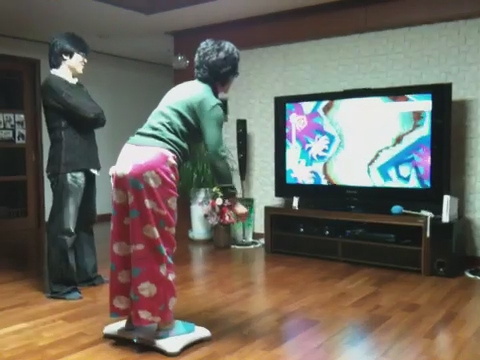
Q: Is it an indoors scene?
A: Yes, it is indoors.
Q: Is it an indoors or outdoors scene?
A: It is indoors.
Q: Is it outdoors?
A: No, it is indoors.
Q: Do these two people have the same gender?
A: No, they are both male and female.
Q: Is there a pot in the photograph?
A: Yes, there is a pot.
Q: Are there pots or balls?
A: Yes, there is a pot.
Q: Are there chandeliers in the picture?
A: No, there are no chandeliers.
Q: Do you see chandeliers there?
A: No, there are no chandeliers.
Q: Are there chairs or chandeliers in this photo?
A: No, there are no chandeliers or chairs.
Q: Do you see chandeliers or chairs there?
A: No, there are no chandeliers or chairs.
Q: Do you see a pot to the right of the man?
A: Yes, there is a pot to the right of the man.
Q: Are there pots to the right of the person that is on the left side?
A: Yes, there is a pot to the right of the man.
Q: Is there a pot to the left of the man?
A: No, the pot is to the right of the man.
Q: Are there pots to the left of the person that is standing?
A: No, the pot is to the right of the man.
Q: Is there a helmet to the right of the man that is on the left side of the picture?
A: No, there is a pot to the right of the man.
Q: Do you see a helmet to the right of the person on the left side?
A: No, there is a pot to the right of the man.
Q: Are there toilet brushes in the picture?
A: No, there are no toilet brushes.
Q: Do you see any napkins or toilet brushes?
A: No, there are no toilet brushes or napkins.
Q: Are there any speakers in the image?
A: Yes, there is a speaker.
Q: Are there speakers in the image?
A: Yes, there is a speaker.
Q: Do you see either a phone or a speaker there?
A: Yes, there is a speaker.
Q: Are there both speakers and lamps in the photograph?
A: No, there is a speaker but no lamps.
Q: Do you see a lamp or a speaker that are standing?
A: Yes, the speaker is standing.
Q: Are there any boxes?
A: No, there are no boxes.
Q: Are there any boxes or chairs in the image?
A: No, there are no boxes or chairs.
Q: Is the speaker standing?
A: Yes, the speaker is standing.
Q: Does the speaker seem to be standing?
A: Yes, the speaker is standing.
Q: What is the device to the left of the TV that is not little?
A: The device is a speaker.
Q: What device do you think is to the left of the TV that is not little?
A: The device is a speaker.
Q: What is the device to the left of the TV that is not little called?
A: The device is a speaker.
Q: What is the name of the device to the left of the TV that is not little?
A: The device is a speaker.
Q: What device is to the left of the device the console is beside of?
A: The device is a speaker.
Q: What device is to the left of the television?
A: The device is a speaker.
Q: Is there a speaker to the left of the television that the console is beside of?
A: Yes, there is a speaker to the left of the TV.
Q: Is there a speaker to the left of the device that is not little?
A: Yes, there is a speaker to the left of the TV.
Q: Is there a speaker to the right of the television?
A: No, the speaker is to the left of the television.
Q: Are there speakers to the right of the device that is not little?
A: No, the speaker is to the left of the television.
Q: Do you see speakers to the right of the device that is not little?
A: No, the speaker is to the left of the television.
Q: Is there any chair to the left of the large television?
A: No, there is a speaker to the left of the television.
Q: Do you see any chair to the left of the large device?
A: No, there is a speaker to the left of the television.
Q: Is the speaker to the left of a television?
A: Yes, the speaker is to the left of a television.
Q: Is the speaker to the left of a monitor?
A: No, the speaker is to the left of a television.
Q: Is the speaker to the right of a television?
A: No, the speaker is to the left of a television.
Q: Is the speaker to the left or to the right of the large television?
A: The speaker is to the left of the TV.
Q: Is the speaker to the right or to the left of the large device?
A: The speaker is to the left of the TV.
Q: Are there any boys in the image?
A: No, there are no boys.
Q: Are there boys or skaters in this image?
A: No, there are no boys or skaters.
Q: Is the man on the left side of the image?
A: Yes, the man is on the left of the image.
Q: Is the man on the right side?
A: No, the man is on the left of the image.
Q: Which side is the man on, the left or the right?
A: The man is on the left of the image.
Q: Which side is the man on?
A: The man is on the left of the image.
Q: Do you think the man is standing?
A: Yes, the man is standing.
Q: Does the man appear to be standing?
A: Yes, the man is standing.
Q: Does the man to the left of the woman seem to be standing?
A: Yes, the man is standing.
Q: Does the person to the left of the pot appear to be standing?
A: Yes, the man is standing.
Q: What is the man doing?
A: The man is standing.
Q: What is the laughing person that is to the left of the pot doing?
A: The man is standing.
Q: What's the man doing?
A: The man is standing.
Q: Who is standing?
A: The man is standing.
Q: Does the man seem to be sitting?
A: No, the man is standing.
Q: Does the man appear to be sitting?
A: No, the man is standing.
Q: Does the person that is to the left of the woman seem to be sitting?
A: No, the man is standing.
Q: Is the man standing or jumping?
A: The man is standing.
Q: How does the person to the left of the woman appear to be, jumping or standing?
A: The man is standing.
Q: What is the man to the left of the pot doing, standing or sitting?
A: The man is standing.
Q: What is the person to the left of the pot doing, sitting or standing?
A: The man is standing.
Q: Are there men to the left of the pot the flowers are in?
A: Yes, there is a man to the left of the pot.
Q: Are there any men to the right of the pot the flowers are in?
A: No, the man is to the left of the pot.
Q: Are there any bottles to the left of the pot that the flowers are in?
A: No, there is a man to the left of the pot.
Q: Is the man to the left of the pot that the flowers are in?
A: Yes, the man is to the left of the pot.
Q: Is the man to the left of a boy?
A: No, the man is to the left of the pot.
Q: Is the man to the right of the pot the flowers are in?
A: No, the man is to the left of the pot.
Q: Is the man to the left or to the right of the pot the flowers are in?
A: The man is to the left of the pot.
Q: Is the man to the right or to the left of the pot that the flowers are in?
A: The man is to the left of the pot.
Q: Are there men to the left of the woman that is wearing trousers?
A: Yes, there is a man to the left of the woman.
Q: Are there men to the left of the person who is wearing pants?
A: Yes, there is a man to the left of the woman.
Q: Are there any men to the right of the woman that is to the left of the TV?
A: No, the man is to the left of the woman.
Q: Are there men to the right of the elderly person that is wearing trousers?
A: No, the man is to the left of the woman.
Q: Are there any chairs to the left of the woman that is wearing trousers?
A: No, there is a man to the left of the woman.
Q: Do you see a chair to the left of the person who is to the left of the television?
A: No, there is a man to the left of the woman.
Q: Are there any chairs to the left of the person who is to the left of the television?
A: No, there is a man to the left of the woman.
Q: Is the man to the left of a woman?
A: Yes, the man is to the left of a woman.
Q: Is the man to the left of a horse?
A: No, the man is to the left of a woman.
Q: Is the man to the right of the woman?
A: No, the man is to the left of the woman.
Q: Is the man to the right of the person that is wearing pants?
A: No, the man is to the left of the woman.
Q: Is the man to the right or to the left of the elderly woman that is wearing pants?
A: The man is to the left of the woman.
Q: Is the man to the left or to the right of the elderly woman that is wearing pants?
A: The man is to the left of the woman.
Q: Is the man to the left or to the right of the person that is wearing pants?
A: The man is to the left of the woman.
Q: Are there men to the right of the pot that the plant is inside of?
A: No, the man is to the left of the pot.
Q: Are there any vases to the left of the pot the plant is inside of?
A: No, there is a man to the left of the pot.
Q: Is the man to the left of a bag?
A: No, the man is to the left of the pot.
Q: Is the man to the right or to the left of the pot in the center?
A: The man is to the left of the pot.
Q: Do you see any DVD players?
A: No, there are no DVD players.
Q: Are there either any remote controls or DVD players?
A: No, there are no DVD players or remote controls.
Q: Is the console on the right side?
A: Yes, the console is on the right of the image.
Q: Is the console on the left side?
A: No, the console is on the right of the image.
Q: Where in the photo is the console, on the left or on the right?
A: The console is on the right of the image.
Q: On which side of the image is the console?
A: The console is on the right of the image.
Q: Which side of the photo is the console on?
A: The console is on the right of the image.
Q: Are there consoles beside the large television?
A: Yes, there is a console beside the TV.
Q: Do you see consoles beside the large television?
A: Yes, there is a console beside the TV.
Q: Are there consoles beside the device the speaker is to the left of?
A: Yes, there is a console beside the TV.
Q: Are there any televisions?
A: Yes, there is a television.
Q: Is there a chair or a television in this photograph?
A: Yes, there is a television.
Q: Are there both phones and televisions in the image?
A: No, there is a television but no phones.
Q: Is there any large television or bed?
A: Yes, there is a large television.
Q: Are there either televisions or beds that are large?
A: Yes, the television is large.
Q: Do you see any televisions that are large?
A: Yes, there is a large television.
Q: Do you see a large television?
A: Yes, there is a large television.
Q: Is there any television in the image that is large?
A: Yes, there is a television that is large.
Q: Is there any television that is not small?
A: Yes, there is a large television.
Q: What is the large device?
A: The device is a television.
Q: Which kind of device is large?
A: The device is a television.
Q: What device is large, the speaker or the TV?
A: The TV is large.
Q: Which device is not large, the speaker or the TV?
A: The speaker is not large.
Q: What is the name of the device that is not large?
A: The device is a speaker.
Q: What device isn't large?
A: The device is a speaker.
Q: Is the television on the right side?
A: Yes, the television is on the right of the image.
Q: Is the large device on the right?
A: Yes, the television is on the right of the image.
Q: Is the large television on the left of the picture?
A: No, the TV is on the right of the image.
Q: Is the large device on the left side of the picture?
A: No, the TV is on the right of the image.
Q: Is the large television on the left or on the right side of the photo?
A: The television is on the right of the image.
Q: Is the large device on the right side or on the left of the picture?
A: The television is on the right of the image.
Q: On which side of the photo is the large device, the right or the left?
A: The television is on the right of the image.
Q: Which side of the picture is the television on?
A: The television is on the right of the image.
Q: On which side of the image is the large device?
A: The television is on the right of the image.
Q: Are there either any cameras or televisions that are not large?
A: No, there is a television but it is large.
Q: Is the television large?
A: Yes, the television is large.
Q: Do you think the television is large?
A: Yes, the television is large.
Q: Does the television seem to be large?
A: Yes, the television is large.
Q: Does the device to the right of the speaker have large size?
A: Yes, the television is large.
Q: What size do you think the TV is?
A: The TV is large.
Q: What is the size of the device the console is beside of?
A: The TV is large.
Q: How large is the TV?
A: The TV is large.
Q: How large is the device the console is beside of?
A: The TV is large.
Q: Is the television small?
A: No, the television is large.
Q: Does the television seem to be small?
A: No, the television is large.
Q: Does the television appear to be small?
A: No, the television is large.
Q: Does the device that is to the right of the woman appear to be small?
A: No, the television is large.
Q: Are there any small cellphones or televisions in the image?
A: No, there is a television but it is large.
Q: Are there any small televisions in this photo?
A: No, there is a television but it is large.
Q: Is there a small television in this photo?
A: No, there is a television but it is large.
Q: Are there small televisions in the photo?
A: No, there is a television but it is large.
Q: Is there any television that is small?
A: No, there is a television but it is large.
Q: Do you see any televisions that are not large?
A: No, there is a television but it is large.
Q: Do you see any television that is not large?
A: No, there is a television but it is large.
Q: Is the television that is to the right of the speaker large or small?
A: The television is large.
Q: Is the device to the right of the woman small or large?
A: The television is large.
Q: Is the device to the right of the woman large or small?
A: The television is large.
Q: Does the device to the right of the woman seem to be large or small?
A: The television is large.